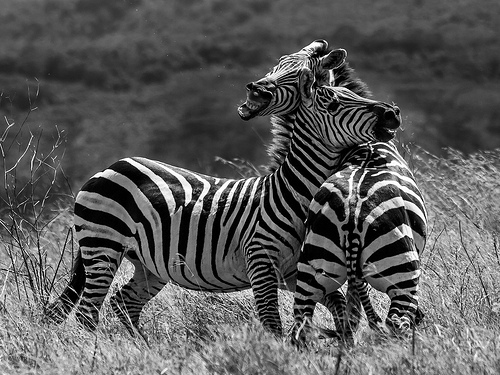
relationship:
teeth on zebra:
[241, 100, 261, 112] [237, 39, 430, 340]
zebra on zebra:
[237, 39, 430, 340] [72, 70, 402, 341]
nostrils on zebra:
[381, 105, 404, 125] [237, 39, 430, 340]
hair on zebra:
[334, 64, 373, 100] [237, 39, 430, 340]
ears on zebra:
[307, 37, 349, 69] [237, 39, 430, 340]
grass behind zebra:
[0, 96, 53, 374] [237, 39, 430, 340]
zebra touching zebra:
[237, 39, 430, 340] [72, 70, 402, 341]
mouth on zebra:
[236, 81, 271, 122] [237, 39, 430, 340]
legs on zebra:
[76, 239, 117, 333] [237, 39, 430, 340]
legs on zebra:
[111, 264, 169, 343] [237, 39, 430, 340]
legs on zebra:
[242, 242, 286, 335] [237, 39, 430, 340]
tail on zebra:
[347, 237, 382, 331] [237, 39, 430, 340]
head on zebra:
[289, 70, 405, 155] [237, 39, 430, 340]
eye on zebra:
[329, 96, 340, 113] [237, 39, 430, 340]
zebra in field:
[237, 39, 430, 340] [4, 4, 281, 176]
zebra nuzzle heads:
[237, 39, 430, 340] [234, 47, 406, 150]